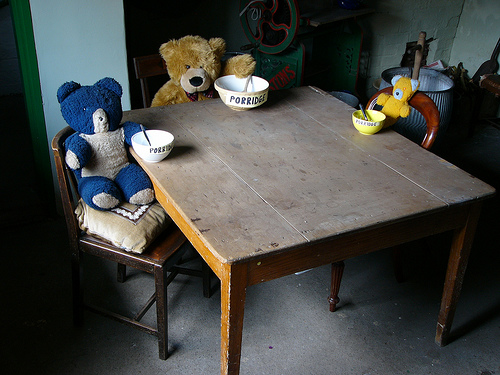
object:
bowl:
[351, 109, 388, 136]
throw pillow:
[73, 195, 170, 255]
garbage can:
[377, 65, 456, 136]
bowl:
[213, 74, 271, 113]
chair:
[363, 85, 442, 151]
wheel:
[238, 0, 301, 56]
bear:
[56, 77, 155, 212]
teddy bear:
[150, 34, 257, 106]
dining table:
[121, 83, 497, 374]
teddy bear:
[376, 74, 420, 131]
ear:
[92, 76, 123, 99]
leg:
[220, 259, 249, 375]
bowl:
[130, 129, 174, 164]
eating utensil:
[139, 123, 154, 148]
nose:
[188, 76, 204, 88]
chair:
[50, 125, 212, 360]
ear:
[410, 78, 421, 94]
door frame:
[9, 0, 58, 224]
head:
[56, 76, 123, 134]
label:
[225, 89, 269, 108]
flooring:
[3, 230, 498, 375]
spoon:
[240, 73, 253, 94]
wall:
[28, 0, 132, 215]